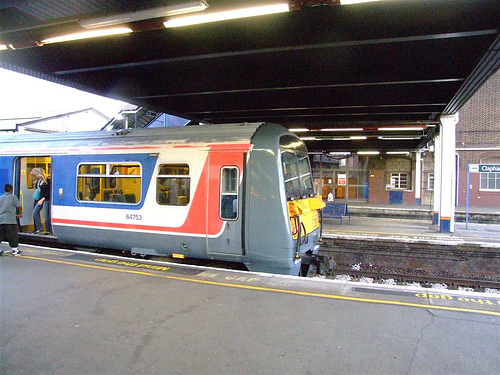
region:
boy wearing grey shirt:
[2, 206, 14, 217]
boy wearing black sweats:
[7, 231, 15, 238]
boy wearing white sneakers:
[6, 243, 23, 260]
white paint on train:
[149, 211, 166, 219]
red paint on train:
[197, 219, 202, 226]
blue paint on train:
[57, 166, 71, 182]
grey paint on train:
[257, 222, 269, 239]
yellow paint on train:
[306, 214, 314, 221]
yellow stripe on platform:
[268, 291, 343, 296]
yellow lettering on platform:
[89, 251, 179, 276]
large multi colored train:
[15, 132, 342, 257]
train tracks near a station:
[370, 236, 485, 286]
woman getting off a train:
[20, 159, 58, 225]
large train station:
[316, 113, 485, 222]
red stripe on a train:
[47, 119, 374, 276]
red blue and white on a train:
[51, 148, 271, 240]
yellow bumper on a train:
[283, 195, 343, 235]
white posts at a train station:
[431, 115, 464, 240]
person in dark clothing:
[0, 188, 32, 255]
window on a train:
[62, 150, 172, 219]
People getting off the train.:
[20, 162, 56, 243]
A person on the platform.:
[1, 189, 38, 260]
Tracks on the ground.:
[359, 247, 498, 293]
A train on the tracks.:
[54, 126, 333, 273]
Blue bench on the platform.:
[320, 197, 357, 222]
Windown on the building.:
[384, 172, 411, 197]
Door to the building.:
[327, 159, 354, 199]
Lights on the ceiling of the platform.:
[56, 19, 256, 43]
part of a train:
[263, 200, 264, 207]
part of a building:
[442, 128, 444, 138]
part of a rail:
[352, 261, 357, 271]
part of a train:
[283, 228, 287, 248]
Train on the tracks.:
[1, 115, 329, 276]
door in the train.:
[10, 151, 65, 241]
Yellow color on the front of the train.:
[285, 185, 326, 237]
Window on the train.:
[70, 158, 147, 209]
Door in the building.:
[311, 163, 376, 203]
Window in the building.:
[384, 168, 411, 192]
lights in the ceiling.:
[33, 0, 309, 55]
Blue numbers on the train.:
[122, 210, 144, 223]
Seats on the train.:
[107, 185, 136, 205]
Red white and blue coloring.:
[47, 138, 249, 245]